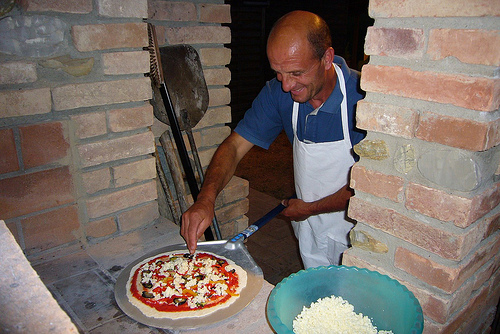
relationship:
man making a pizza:
[178, 8, 360, 266] [125, 247, 250, 322]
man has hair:
[178, 8, 360, 266] [306, 19, 334, 62]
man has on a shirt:
[178, 8, 360, 266] [233, 56, 366, 150]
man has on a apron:
[178, 8, 360, 266] [288, 64, 355, 266]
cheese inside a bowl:
[293, 295, 396, 334] [264, 263, 425, 334]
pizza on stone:
[125, 247, 250, 322] [33, 218, 265, 333]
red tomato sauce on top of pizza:
[147, 299, 189, 312] [125, 247, 250, 322]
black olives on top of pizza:
[140, 278, 155, 301] [125, 247, 250, 322]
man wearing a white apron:
[178, 8, 360, 266] [288, 64, 355, 266]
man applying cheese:
[178, 8, 360, 266] [307, 311, 354, 333]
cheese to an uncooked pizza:
[307, 311, 354, 333] [125, 247, 250, 322]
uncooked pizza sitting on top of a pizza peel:
[125, 247, 250, 322] [113, 206, 264, 333]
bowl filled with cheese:
[264, 263, 425, 334] [293, 295, 396, 334]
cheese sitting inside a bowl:
[293, 295, 396, 334] [264, 263, 425, 334]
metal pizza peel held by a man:
[113, 206, 264, 333] [178, 8, 360, 266]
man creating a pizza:
[178, 8, 360, 266] [125, 247, 250, 322]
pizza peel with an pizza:
[113, 206, 264, 333] [125, 247, 250, 322]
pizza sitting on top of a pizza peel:
[125, 247, 250, 322] [113, 206, 264, 333]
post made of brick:
[340, 0, 499, 259] [360, 66, 500, 113]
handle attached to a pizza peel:
[252, 202, 281, 231] [113, 206, 264, 333]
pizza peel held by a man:
[113, 206, 264, 333] [178, 8, 360, 266]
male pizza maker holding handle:
[178, 8, 360, 266] [252, 202, 281, 231]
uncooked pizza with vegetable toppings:
[125, 247, 250, 322] [139, 264, 160, 300]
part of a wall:
[2, 0, 102, 130] [1, 0, 152, 215]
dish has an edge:
[264, 263, 425, 334] [268, 263, 407, 293]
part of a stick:
[159, 130, 176, 160] [158, 128, 188, 209]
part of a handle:
[255, 203, 278, 229] [233, 207, 280, 242]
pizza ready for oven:
[125, 247, 250, 322] [0, 219, 81, 333]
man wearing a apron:
[178, 8, 360, 266] [288, 64, 355, 266]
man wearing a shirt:
[178, 8, 360, 266] [233, 56, 366, 150]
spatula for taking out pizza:
[113, 206, 264, 333] [125, 247, 250, 322]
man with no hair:
[178, 8, 360, 266] [266, 8, 309, 54]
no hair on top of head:
[266, 8, 309, 54] [265, 10, 330, 55]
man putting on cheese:
[178, 8, 360, 266] [307, 311, 354, 333]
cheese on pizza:
[167, 257, 191, 278] [125, 247, 250, 322]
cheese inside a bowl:
[307, 311, 354, 333] [264, 263, 425, 334]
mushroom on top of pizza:
[170, 293, 188, 306] [125, 247, 250, 322]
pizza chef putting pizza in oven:
[178, 8, 360, 266] [0, 219, 81, 333]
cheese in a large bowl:
[293, 295, 396, 334] [264, 263, 425, 334]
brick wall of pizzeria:
[1, 0, 152, 215] [2, 1, 499, 330]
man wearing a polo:
[178, 8, 360, 266] [233, 56, 366, 150]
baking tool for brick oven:
[147, 22, 195, 197] [0, 219, 81, 333]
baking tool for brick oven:
[147, 22, 224, 239] [0, 219, 81, 333]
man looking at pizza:
[178, 8, 360, 266] [125, 247, 250, 322]